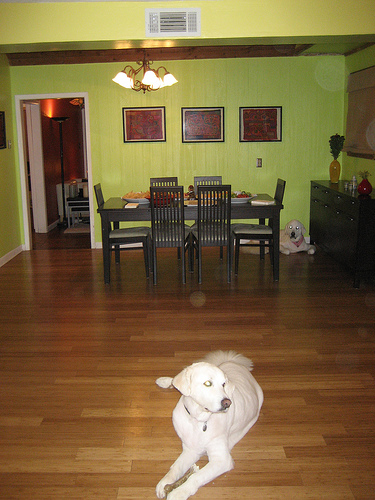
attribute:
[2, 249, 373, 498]
floor — wooden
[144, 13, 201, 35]
vent — gray, metal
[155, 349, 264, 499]
dog — white, yellow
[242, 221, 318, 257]
dog — yellow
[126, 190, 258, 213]
food — good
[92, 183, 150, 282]
chair — black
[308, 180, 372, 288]
hutch — wooden, brown